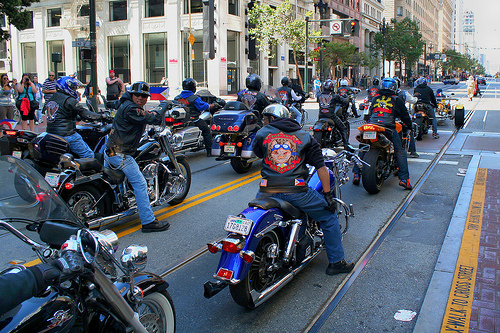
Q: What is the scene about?
A: A bikers race.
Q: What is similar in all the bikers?
A: Their shirts.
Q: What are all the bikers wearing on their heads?
A: Helmets.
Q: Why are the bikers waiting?
A: Because its stop sign.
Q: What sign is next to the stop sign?
A: No left turns.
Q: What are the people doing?
A: Watching the bikers.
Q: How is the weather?
A: Sunny.